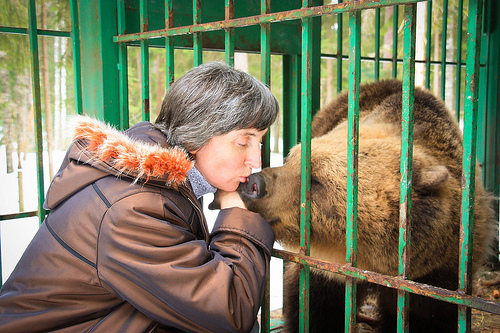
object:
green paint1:
[301, 152, 311, 254]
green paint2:
[346, 150, 357, 269]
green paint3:
[399, 46, 411, 281]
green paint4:
[458, 142, 473, 296]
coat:
[0, 115, 273, 331]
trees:
[0, 1, 83, 200]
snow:
[1, 145, 55, 257]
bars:
[298, 52, 411, 264]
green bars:
[343, 187, 475, 269]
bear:
[239, 80, 498, 332]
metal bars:
[121, 21, 129, 131]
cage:
[0, 3, 500, 333]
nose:
[239, 174, 264, 199]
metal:
[299, 25, 483, 117]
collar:
[186, 166, 217, 199]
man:
[0, 62, 279, 333]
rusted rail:
[112, 0, 382, 47]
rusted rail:
[276, 245, 499, 320]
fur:
[72, 115, 107, 142]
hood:
[40, 99, 195, 210]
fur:
[109, 139, 177, 182]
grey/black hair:
[154, 62, 279, 150]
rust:
[325, 261, 415, 287]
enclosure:
[293, 57, 500, 333]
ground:
[0, 146, 73, 281]